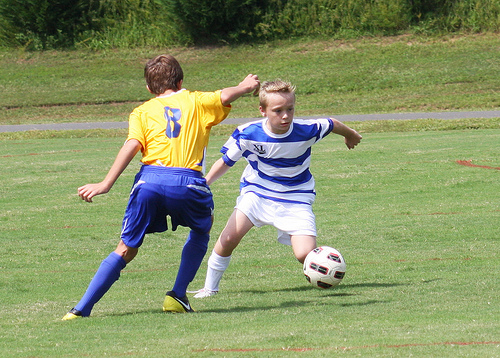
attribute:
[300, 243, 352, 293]
ball — white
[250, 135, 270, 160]
size — XL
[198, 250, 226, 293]
sock — high, white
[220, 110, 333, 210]
striped shirt — yellow, blue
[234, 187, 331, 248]
shorts — sports, white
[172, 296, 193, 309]
nike swoosh — White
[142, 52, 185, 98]
hair — brown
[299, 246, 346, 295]
ball — white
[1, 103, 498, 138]
walkway — grey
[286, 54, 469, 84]
grass — greener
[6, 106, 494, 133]
path — grey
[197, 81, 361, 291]
boy — blonde, white, blue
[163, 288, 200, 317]
shoe — yellow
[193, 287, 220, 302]
shoe — yellow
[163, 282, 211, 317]
nike cleat — yellow, black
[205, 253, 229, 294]
sock — white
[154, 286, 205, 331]
cleats — black, white striped, yellow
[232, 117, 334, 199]
t-shirt — blue, white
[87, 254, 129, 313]
sock — blue, knee length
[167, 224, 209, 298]
sock — blue, knee length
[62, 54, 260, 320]
boy — little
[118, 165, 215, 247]
shorts — blue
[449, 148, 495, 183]
marking — red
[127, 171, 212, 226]
blue shorts — white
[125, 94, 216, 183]
jersey — yellow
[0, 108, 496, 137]
path — paved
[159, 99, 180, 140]
number — blue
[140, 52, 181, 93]
hair — brown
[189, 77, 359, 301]
boy — blonde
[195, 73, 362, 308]
player — opposing